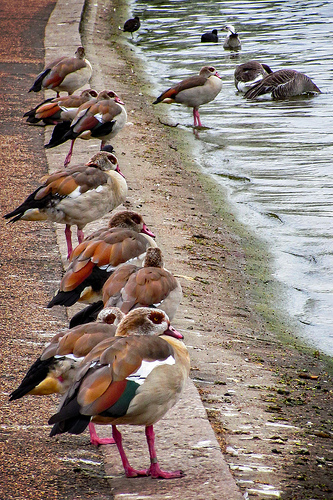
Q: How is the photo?
A: Clear.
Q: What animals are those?
A: Birds.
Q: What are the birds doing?
A: Standing.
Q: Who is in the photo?
A: Nobody.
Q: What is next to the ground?
A: Water.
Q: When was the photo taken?
A: Daytime.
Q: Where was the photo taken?
A: At waters edge.